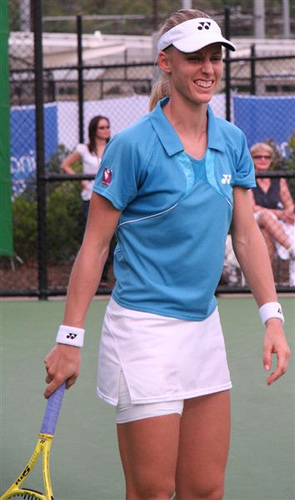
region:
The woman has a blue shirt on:
[101, 111, 261, 330]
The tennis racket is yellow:
[1, 387, 64, 499]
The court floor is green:
[58, 427, 116, 489]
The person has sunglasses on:
[242, 141, 283, 177]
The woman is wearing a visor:
[146, 4, 236, 68]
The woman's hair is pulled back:
[149, 0, 202, 121]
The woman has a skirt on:
[92, 305, 293, 406]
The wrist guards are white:
[250, 296, 292, 342]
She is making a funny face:
[181, 41, 225, 112]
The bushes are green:
[17, 156, 87, 248]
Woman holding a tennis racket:
[1, 7, 292, 498]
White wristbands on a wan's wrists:
[51, 299, 286, 352]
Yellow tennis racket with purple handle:
[3, 382, 71, 498]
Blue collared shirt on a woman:
[89, 93, 259, 322]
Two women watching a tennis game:
[57, 113, 294, 266]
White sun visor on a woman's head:
[155, 16, 237, 56]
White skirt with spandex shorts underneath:
[94, 293, 232, 427]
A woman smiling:
[154, 7, 240, 106]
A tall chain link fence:
[11, 44, 293, 295]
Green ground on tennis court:
[0, 295, 292, 497]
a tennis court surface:
[0, 296, 294, 498]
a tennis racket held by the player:
[0, 381, 67, 499]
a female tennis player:
[43, 8, 290, 498]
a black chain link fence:
[0, 0, 294, 300]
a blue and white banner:
[9, 92, 294, 201]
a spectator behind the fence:
[59, 115, 114, 287]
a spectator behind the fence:
[247, 143, 294, 266]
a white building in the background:
[8, 31, 293, 105]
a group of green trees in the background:
[8, 0, 294, 35]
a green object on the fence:
[0, 0, 13, 257]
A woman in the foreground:
[38, 5, 293, 497]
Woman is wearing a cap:
[150, 14, 243, 75]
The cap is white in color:
[150, 16, 236, 70]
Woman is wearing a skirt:
[98, 293, 253, 428]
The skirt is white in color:
[89, 296, 252, 424]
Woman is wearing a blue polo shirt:
[81, 89, 260, 327]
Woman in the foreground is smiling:
[182, 70, 226, 96]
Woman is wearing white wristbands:
[52, 295, 289, 349]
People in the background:
[56, 107, 293, 262]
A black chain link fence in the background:
[0, 1, 294, 297]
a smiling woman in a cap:
[155, 6, 227, 102]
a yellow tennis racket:
[0, 372, 81, 498]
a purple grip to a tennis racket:
[40, 378, 66, 430]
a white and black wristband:
[54, 325, 87, 346]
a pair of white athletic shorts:
[96, 310, 225, 408]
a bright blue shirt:
[92, 121, 250, 308]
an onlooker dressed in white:
[57, 113, 111, 245]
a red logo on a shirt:
[100, 167, 115, 185]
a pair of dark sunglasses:
[250, 153, 271, 159]